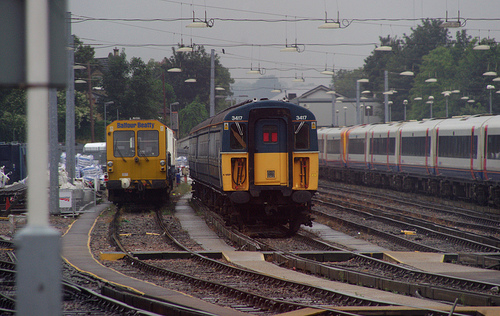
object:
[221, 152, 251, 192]
trim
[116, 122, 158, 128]
writing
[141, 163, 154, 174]
yellow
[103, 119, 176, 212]
car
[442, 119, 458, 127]
white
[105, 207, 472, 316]
curved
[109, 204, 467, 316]
track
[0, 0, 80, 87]
sign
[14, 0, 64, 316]
pole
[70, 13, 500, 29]
power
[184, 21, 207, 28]
lights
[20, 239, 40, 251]
grey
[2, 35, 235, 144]
full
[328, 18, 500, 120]
trees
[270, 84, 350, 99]
house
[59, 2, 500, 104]
sky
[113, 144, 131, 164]
wipers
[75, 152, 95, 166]
bags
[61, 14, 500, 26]
wires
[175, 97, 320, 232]
trains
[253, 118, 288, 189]
door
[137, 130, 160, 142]
windows